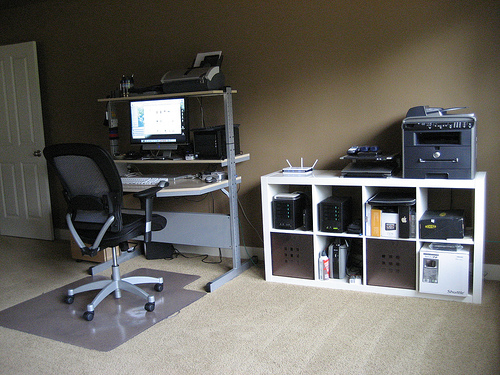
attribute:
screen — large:
[127, 98, 195, 155]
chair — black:
[38, 132, 181, 327]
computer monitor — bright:
[127, 99, 185, 139]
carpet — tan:
[268, 294, 406, 373]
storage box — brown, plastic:
[366, 238, 416, 285]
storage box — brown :
[366, 237, 418, 289]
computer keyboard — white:
[86, 175, 174, 210]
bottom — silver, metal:
[116, 206, 233, 253]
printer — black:
[398, 103, 478, 178]